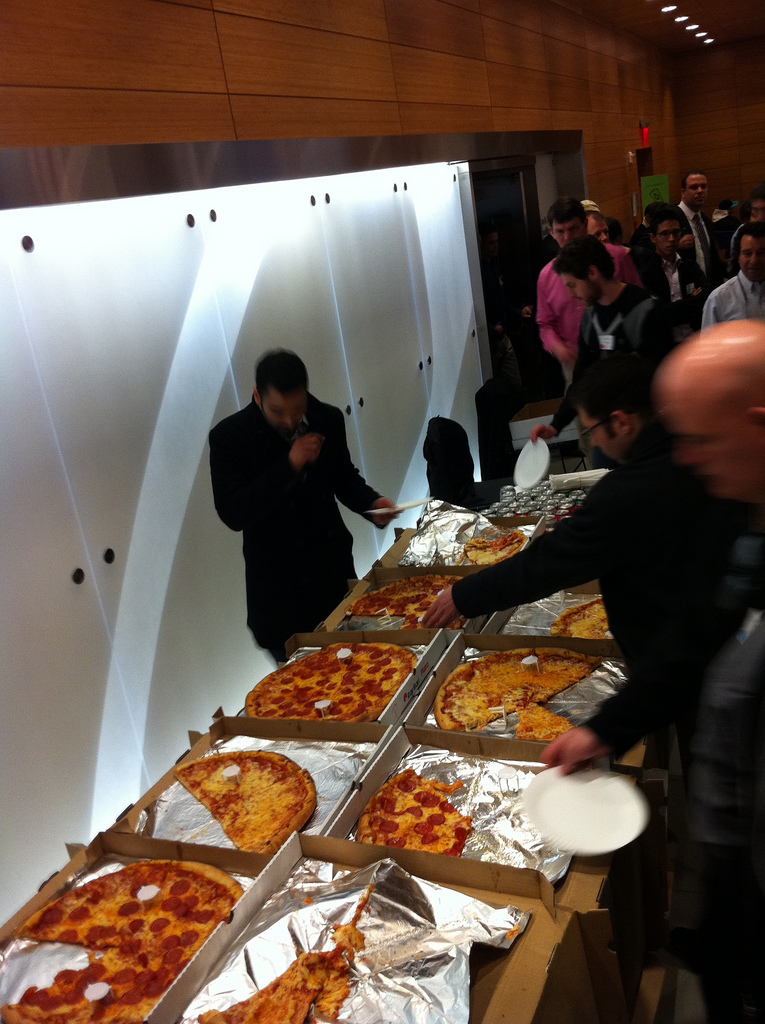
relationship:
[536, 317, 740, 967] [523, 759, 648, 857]
bald man holds a paper plate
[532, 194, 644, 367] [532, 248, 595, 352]
man wearing a pink shirt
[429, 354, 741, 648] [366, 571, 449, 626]
man taking a slice of pizza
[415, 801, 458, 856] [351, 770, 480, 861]
pepperoni on pizza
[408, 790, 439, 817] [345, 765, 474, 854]
pepperoni on pizza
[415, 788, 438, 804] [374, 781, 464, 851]
pepperoni on pizza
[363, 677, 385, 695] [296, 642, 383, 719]
pepperoni on pizza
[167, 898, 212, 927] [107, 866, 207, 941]
pepperoni on pizza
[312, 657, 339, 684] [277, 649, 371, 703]
pepperoni on pizza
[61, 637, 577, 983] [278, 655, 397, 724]
table full of pizza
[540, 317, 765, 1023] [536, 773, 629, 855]
bald man holding plate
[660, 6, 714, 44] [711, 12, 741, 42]
five lights are on ceiling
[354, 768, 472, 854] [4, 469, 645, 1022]
pizza on buffet line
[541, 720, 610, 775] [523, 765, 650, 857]
hand holding paper plate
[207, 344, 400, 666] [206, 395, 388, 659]
man wearing suit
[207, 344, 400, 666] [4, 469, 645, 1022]
man going through buffet line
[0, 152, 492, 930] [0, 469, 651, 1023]
wall next to table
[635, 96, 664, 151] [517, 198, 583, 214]
red exit sign above a door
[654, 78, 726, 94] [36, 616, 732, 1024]
five lights in ceiling of banquet hall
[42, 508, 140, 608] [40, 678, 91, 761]
knobs on folding white wall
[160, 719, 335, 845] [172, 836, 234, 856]
half a cheese pizza in a box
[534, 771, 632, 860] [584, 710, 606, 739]
plate being held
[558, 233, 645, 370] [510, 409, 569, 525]
person picking up a plate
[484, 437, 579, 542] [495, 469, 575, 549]
group of cans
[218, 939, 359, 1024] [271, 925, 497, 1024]
only one slice left in th box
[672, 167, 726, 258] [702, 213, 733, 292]
man wearing a necktie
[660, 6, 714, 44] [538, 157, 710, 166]
five lights colored overhead lighting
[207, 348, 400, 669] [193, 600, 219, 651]
man standing up